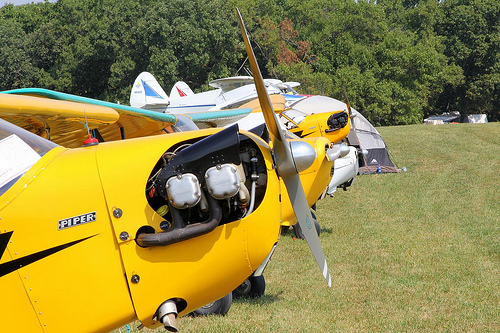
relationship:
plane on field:
[1, 88, 360, 331] [229, 117, 499, 330]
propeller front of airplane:
[231, 5, 335, 289] [0, 6, 335, 332]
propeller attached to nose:
[202, 0, 354, 292] [267, 135, 318, 182]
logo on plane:
[54, 209, 101, 235] [0, 104, 387, 321]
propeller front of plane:
[231, 5, 335, 289] [51, 76, 364, 304]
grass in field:
[168, 119, 497, 331] [112, 122, 499, 332]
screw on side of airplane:
[123, 271, 144, 282] [0, 6, 335, 332]